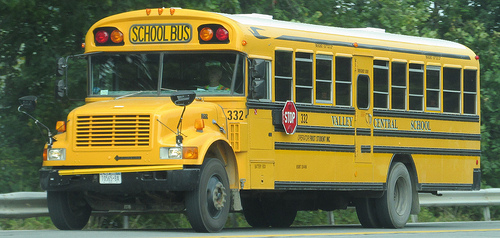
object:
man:
[199, 64, 237, 93]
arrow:
[114, 154, 142, 161]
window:
[273, 48, 294, 103]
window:
[313, 52, 335, 105]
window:
[334, 53, 352, 106]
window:
[354, 74, 371, 110]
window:
[371, 57, 389, 110]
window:
[389, 58, 406, 110]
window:
[426, 62, 442, 112]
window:
[440, 64, 460, 114]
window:
[463, 68, 480, 115]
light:
[199, 27, 214, 42]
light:
[92, 30, 109, 44]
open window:
[295, 49, 316, 105]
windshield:
[91, 49, 246, 96]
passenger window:
[405, 62, 427, 111]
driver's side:
[86, 49, 248, 98]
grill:
[76, 113, 151, 147]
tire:
[371, 161, 412, 229]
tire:
[184, 157, 232, 232]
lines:
[76, 114, 150, 124]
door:
[349, 53, 374, 163]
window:
[246, 57, 271, 102]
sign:
[280, 100, 298, 135]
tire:
[47, 190, 91, 231]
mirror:
[169, 89, 196, 145]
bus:
[17, 7, 482, 234]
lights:
[109, 29, 124, 43]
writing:
[329, 115, 353, 126]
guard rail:
[0, 187, 499, 230]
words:
[131, 24, 189, 42]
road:
[0, 220, 499, 238]